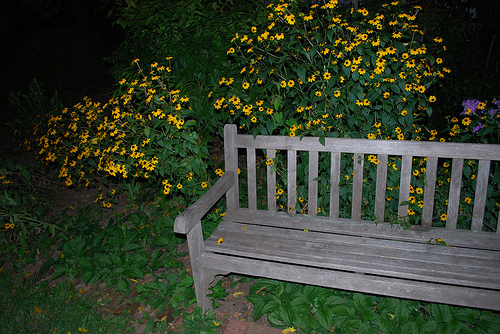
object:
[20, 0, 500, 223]
bouquet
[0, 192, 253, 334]
dirt patches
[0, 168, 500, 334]
weeds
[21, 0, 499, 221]
flower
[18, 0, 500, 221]
bush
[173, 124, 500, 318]
bench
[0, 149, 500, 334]
ground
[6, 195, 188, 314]
leaves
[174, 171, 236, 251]
rest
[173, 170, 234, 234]
bench arms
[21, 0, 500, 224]
flower bush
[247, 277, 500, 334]
leaves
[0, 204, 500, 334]
grass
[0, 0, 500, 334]
green shrubs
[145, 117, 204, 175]
leaves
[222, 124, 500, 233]
wooden back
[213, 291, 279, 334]
dirt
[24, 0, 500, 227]
daisy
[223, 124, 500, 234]
back rest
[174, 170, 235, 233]
arm rest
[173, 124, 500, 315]
wooden seat